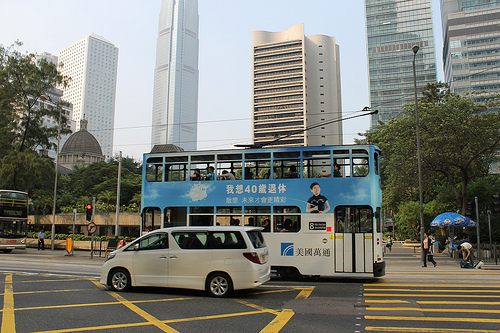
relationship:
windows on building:
[461, 35, 498, 46] [30, 5, 498, 179]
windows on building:
[368, 37, 431, 53] [30, 5, 498, 179]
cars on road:
[36, 223, 260, 328] [0, 264, 499, 331]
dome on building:
[56, 116, 104, 156] [56, 114, 105, 173]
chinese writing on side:
[225, 182, 287, 205] [139, 142, 385, 276]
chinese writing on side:
[293, 247, 330, 257] [139, 142, 385, 276]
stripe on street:
[362, 282, 499, 287] [1, 270, 499, 330]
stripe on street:
[363, 292, 499, 298] [1, 270, 499, 330]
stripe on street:
[365, 307, 499, 314] [1, 270, 499, 330]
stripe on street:
[364, 314, 499, 323] [1, 270, 499, 330]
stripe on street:
[364, 326, 499, 331] [1, 270, 499, 330]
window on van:
[252, 230, 262, 244] [99, 224, 269, 296]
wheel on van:
[207, 273, 234, 299] [99, 224, 269, 296]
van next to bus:
[85, 224, 285, 311] [132, 143, 382, 279]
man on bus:
[304, 180, 333, 213] [132, 143, 382, 279]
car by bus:
[98, 225, 269, 296] [168, 153, 440, 272]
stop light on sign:
[71, 197, 103, 225] [77, 216, 113, 246]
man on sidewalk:
[29, 227, 51, 249] [25, 228, 487, 271]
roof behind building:
[62, 113, 105, 154] [53, 112, 105, 175]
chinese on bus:
[292, 243, 304, 262] [140, 149, 387, 276]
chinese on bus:
[302, 245, 312, 258] [140, 149, 387, 276]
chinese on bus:
[314, 247, 322, 260] [140, 149, 387, 276]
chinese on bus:
[319, 248, 330, 258] [140, 149, 387, 276]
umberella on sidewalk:
[429, 210, 477, 228] [389, 263, 498, 270]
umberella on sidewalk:
[429, 210, 477, 228] [387, 255, 419, 272]